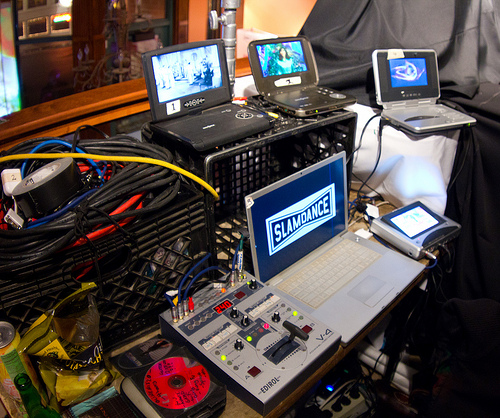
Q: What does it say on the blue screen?
A: SLAMDANCE.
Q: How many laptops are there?
A: One.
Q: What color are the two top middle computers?
A: Black.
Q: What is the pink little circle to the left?
A: CD.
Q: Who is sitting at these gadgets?
A: No one.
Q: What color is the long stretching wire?
A: Yellow.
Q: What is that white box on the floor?
A: Outlet.